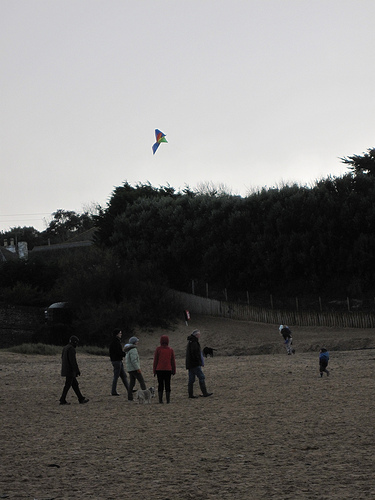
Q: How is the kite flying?
A: Wind.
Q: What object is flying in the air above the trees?
A: Kite.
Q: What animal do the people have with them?
A: A dog.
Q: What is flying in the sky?
A: Kite.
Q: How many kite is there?
A: One.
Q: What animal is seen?
A: Dog.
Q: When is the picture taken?
A: Daytime.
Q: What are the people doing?
A: Walking.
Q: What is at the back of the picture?
A: Trees.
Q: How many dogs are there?
A: 1.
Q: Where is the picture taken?
A: In a field.